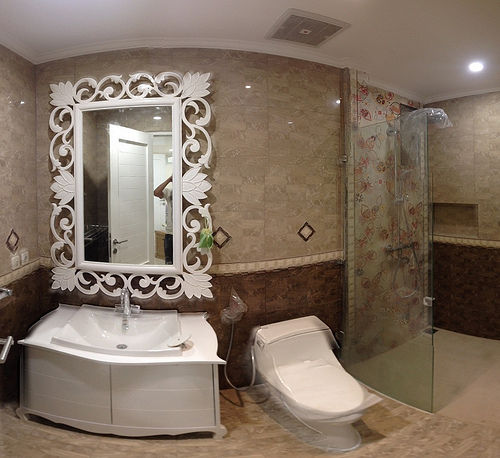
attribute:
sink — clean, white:
[23, 289, 226, 366]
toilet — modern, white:
[250, 313, 382, 452]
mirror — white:
[48, 73, 213, 299]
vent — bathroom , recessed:
[268, 9, 352, 46]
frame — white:
[50, 83, 214, 299]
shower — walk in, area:
[348, 68, 499, 423]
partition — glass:
[343, 114, 434, 413]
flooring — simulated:
[0, 326, 498, 457]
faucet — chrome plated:
[116, 290, 139, 317]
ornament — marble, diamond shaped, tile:
[299, 222, 315, 242]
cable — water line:
[225, 299, 258, 394]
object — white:
[419, 323, 438, 337]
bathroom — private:
[1, 0, 498, 457]